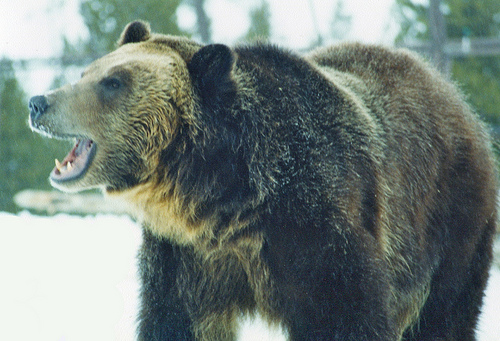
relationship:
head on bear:
[20, 13, 236, 209] [23, 18, 494, 340]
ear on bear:
[114, 18, 152, 47] [23, 18, 494, 340]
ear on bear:
[188, 42, 237, 102] [23, 18, 494, 340]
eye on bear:
[102, 75, 119, 89] [23, 18, 494, 340]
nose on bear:
[24, 92, 50, 119] [23, 18, 494, 340]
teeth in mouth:
[54, 158, 70, 174] [24, 113, 97, 186]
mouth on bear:
[28, 118, 104, 187] [23, 18, 494, 340]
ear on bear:
[114, 18, 157, 57] [23, 18, 494, 340]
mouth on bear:
[21, 117, 104, 187] [23, 18, 494, 340]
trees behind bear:
[55, 2, 215, 201] [23, 18, 494, 340]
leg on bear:
[277, 289, 416, 340] [23, 18, 494, 340]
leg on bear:
[132, 296, 235, 340] [23, 18, 494, 340]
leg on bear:
[407, 269, 487, 339] [23, 18, 494, 340]